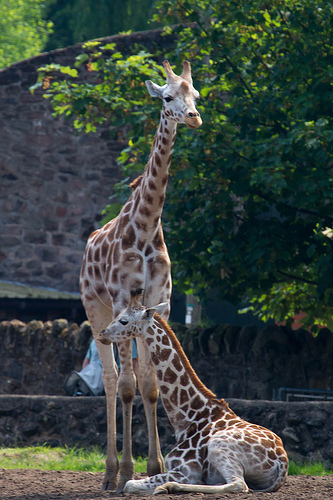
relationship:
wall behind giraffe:
[1, 17, 206, 297] [79, 59, 201, 496]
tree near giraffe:
[38, 4, 329, 327] [79, 59, 201, 496]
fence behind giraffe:
[0, 314, 331, 461] [83, 285, 299, 499]